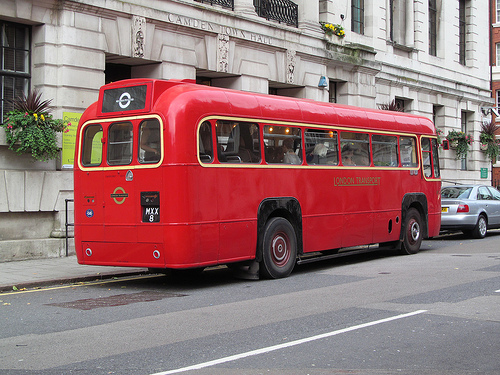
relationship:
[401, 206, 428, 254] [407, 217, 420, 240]
tires has caps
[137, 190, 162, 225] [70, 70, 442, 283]
tag on bus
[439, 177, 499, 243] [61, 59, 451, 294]
automobile in front of bus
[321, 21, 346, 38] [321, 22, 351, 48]
flowers in box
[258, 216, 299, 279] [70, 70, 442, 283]
tire on bus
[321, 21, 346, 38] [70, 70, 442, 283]
flowers next to bus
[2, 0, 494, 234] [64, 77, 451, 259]
building behind bus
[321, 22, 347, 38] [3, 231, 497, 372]
box on road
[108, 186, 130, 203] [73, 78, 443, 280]
logo on bus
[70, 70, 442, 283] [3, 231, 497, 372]
bus on road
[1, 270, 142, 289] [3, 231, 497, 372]
curb on road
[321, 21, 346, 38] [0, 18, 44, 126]
flowers on window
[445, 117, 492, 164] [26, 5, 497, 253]
plants on building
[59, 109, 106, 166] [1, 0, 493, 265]
sign on building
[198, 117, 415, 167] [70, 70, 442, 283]
windows on bus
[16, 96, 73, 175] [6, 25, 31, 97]
flowers on window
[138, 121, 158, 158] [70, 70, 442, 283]
person on bus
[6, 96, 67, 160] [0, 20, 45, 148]
flowers in window box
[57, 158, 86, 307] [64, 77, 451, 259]
rail behind bus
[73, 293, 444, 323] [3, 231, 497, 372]
line on road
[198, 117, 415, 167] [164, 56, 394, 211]
windows on bus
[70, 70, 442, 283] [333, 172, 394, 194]
bus belongs to london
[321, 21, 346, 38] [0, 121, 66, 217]
flowers growing on sil